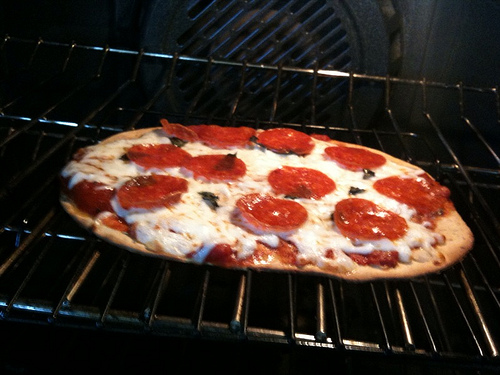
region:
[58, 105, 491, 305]
pizza sitting on the rack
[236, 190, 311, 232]
slice of pepperoni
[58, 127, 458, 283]
pepperoni on top of the pizza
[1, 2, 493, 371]
pizza sitting in the oven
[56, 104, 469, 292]
cheese on top of the pizza is melted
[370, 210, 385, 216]
light glare on the pepperoni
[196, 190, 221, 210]
small dark green leaf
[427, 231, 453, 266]
cheese on the crust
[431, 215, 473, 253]
large hunk of crust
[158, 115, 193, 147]
pepperoni is sticking up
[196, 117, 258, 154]
The sliced pepperoni is round.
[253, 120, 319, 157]
The sliced pepperoni is round.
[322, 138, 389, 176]
The sliced pepperoni is round.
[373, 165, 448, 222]
The sliced pepperoni is round.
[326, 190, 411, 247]
The sliced pepperoni is round.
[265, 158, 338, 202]
The sliced pepperoni is round.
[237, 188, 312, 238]
The sliced pepperoni is round.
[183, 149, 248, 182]
The sliced pepperoni is round.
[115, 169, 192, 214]
The sliced pepperoni is round.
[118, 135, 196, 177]
The sliced pepperoni is round.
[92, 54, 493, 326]
pizza is in the oven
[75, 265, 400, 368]
the oven rack is black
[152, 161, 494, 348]
pepperoni is on the pizza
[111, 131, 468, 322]
anchovies are on the pizza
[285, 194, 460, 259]
the crust is toasted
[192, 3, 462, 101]
the heater on the oven is on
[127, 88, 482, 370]
the cheese has melted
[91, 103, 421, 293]
the pepperoni is red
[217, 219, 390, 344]
sauce is on the pizza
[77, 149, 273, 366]
the crust is thin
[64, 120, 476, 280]
a small pizza inside an oven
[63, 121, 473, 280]
a thin pizza with pepperoni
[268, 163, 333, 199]
a slice of pepperoni on a pizza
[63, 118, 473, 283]
a pizza on an oven grill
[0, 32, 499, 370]
a metal oven grill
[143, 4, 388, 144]
a vent inside an oven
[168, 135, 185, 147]
bit of cooked basil leaf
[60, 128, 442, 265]
cheese on a pizza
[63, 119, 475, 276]
pepperoni slices on a pizza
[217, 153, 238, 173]
a basil leaf behind a pepperoni slice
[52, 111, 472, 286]
Pepperoni pizza heating in oven